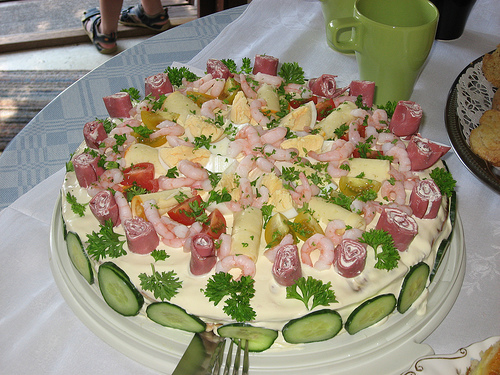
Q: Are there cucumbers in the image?
A: Yes, there is a cucumber.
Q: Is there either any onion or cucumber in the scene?
A: Yes, there is a cucumber.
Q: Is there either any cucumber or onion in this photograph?
A: Yes, there is a cucumber.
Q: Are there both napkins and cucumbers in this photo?
A: No, there is a cucumber but no napkins.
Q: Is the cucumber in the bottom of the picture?
A: Yes, the cucumber is in the bottom of the image.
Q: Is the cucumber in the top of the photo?
A: No, the cucumber is in the bottom of the image.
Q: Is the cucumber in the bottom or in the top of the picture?
A: The cucumber is in the bottom of the image.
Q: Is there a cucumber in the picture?
A: Yes, there is a cucumber.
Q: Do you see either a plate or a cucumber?
A: Yes, there is a cucumber.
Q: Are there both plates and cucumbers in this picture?
A: Yes, there are both a cucumber and a plate.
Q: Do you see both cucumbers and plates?
A: Yes, there are both a cucumber and a plate.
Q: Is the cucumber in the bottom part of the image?
A: Yes, the cucumber is in the bottom of the image.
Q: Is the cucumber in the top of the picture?
A: No, the cucumber is in the bottom of the image.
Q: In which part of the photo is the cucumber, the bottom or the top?
A: The cucumber is in the bottom of the image.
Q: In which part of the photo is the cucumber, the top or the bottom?
A: The cucumber is in the bottom of the image.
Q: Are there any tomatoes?
A: Yes, there are tomatoes.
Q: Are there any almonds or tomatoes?
A: Yes, there are tomatoes.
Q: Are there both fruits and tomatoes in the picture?
A: No, there are tomatoes but no fruits.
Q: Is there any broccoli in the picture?
A: No, there is no broccoli.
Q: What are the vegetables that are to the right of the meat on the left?
A: The vegetables are tomatoes.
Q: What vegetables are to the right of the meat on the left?
A: The vegetables are tomatoes.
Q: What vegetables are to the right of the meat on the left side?
A: The vegetables are tomatoes.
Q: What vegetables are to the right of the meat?
A: The vegetables are tomatoes.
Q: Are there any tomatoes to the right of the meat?
A: Yes, there are tomatoes to the right of the meat.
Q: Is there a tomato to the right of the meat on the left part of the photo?
A: Yes, there are tomatoes to the right of the meat.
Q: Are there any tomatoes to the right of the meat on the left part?
A: Yes, there are tomatoes to the right of the meat.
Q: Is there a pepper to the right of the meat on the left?
A: No, there are tomatoes to the right of the meat.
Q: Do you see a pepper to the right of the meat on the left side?
A: No, there are tomatoes to the right of the meat.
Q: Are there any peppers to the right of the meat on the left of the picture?
A: No, there are tomatoes to the right of the meat.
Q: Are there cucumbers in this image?
A: Yes, there is a cucumber.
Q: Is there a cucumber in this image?
A: Yes, there is a cucumber.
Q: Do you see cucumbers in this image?
A: Yes, there is a cucumber.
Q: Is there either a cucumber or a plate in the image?
A: Yes, there is a cucumber.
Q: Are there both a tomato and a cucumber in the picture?
A: Yes, there are both a cucumber and a tomato.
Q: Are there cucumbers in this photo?
A: Yes, there is a cucumber.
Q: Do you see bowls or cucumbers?
A: Yes, there is a cucumber.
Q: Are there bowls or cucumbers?
A: Yes, there is a cucumber.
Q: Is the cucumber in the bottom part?
A: Yes, the cucumber is in the bottom of the image.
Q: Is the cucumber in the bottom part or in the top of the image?
A: The cucumber is in the bottom of the image.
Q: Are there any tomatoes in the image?
A: Yes, there are tomatoes.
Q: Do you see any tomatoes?
A: Yes, there are tomatoes.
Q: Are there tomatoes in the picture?
A: Yes, there are tomatoes.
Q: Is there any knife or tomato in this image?
A: Yes, there are tomatoes.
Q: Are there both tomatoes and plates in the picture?
A: Yes, there are both tomatoes and a plate.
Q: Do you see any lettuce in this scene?
A: No, there is no lettuce.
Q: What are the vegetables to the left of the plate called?
A: The vegetables are tomatoes.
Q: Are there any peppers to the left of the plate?
A: No, there are tomatoes to the left of the plate.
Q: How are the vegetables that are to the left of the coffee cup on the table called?
A: The vegetables are tomatoes.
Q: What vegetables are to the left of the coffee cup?
A: The vegetables are tomatoes.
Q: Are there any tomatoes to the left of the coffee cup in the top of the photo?
A: Yes, there are tomatoes to the left of the coffee cup.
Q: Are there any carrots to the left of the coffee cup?
A: No, there are tomatoes to the left of the coffee cup.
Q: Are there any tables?
A: Yes, there is a table.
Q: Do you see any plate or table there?
A: Yes, there is a table.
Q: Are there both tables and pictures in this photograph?
A: No, there is a table but no pictures.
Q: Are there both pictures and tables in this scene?
A: No, there is a table but no pictures.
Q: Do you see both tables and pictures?
A: No, there is a table but no pictures.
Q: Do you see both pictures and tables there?
A: No, there is a table but no pictures.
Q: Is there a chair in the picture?
A: No, there are no chairs.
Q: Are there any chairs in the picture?
A: No, there are no chairs.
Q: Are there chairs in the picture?
A: No, there are no chairs.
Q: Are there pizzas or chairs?
A: No, there are no chairs or pizzas.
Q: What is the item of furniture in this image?
A: The piece of furniture is a table.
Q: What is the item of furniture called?
A: The piece of furniture is a table.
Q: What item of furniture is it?
A: The piece of furniture is a table.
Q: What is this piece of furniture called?
A: This is a table.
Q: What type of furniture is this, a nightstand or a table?
A: This is a table.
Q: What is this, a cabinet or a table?
A: This is a table.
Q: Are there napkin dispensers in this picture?
A: No, there are no napkin dispensers.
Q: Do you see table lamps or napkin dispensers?
A: No, there are no napkin dispensers or table lamps.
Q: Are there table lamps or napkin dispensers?
A: No, there are no napkin dispensers or table lamps.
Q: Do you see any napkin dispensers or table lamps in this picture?
A: No, there are no napkin dispensers or table lamps.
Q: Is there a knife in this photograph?
A: Yes, there is a knife.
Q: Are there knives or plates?
A: Yes, there is a knife.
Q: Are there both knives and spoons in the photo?
A: No, there is a knife but no spoons.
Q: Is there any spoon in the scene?
A: No, there are no spoons.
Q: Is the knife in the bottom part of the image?
A: Yes, the knife is in the bottom of the image.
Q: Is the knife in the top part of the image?
A: No, the knife is in the bottom of the image.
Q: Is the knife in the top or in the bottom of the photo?
A: The knife is in the bottom of the image.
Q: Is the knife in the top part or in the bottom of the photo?
A: The knife is in the bottom of the image.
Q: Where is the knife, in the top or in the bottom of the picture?
A: The knife is in the bottom of the image.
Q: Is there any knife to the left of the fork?
A: Yes, there is a knife to the left of the fork.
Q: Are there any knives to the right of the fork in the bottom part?
A: No, the knife is to the left of the fork.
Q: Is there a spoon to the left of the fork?
A: No, there is a knife to the left of the fork.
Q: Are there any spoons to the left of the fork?
A: No, there is a knife to the left of the fork.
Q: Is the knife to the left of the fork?
A: Yes, the knife is to the left of the fork.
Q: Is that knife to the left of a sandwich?
A: No, the knife is to the left of the fork.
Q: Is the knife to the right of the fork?
A: No, the knife is to the left of the fork.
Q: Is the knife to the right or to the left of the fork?
A: The knife is to the left of the fork.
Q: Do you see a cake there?
A: Yes, there is a cake.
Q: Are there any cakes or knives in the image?
A: Yes, there is a cake.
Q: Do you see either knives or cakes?
A: Yes, there is a cake.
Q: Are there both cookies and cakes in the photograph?
A: Yes, there are both a cake and a cookie.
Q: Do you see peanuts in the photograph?
A: No, there are no peanuts.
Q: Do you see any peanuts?
A: No, there are no peanuts.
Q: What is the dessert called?
A: The dessert is a cake.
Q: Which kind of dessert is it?
A: The dessert is a cake.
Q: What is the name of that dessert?
A: This is a cake.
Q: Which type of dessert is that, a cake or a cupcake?
A: This is a cake.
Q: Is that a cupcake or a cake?
A: That is a cake.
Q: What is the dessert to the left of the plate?
A: The dessert is a cake.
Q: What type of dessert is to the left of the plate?
A: The dessert is a cake.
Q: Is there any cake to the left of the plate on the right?
A: Yes, there is a cake to the left of the plate.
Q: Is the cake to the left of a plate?
A: Yes, the cake is to the left of a plate.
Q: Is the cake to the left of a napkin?
A: No, the cake is to the left of a plate.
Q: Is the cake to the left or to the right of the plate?
A: The cake is to the left of the plate.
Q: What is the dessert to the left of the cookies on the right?
A: The dessert is a cake.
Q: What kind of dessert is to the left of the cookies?
A: The dessert is a cake.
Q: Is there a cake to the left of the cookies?
A: Yes, there is a cake to the left of the cookies.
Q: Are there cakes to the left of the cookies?
A: Yes, there is a cake to the left of the cookies.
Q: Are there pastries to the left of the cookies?
A: No, there is a cake to the left of the cookies.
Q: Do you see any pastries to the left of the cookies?
A: No, there is a cake to the left of the cookies.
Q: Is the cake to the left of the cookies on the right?
A: Yes, the cake is to the left of the cookies.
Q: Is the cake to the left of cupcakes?
A: No, the cake is to the left of the cookies.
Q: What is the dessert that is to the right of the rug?
A: The dessert is a cake.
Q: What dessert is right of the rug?
A: The dessert is a cake.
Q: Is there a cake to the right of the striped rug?
A: Yes, there is a cake to the right of the rug.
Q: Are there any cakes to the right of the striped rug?
A: Yes, there is a cake to the right of the rug.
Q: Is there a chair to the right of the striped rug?
A: No, there is a cake to the right of the rug.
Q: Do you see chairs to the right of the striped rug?
A: No, there is a cake to the right of the rug.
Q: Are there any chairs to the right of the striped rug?
A: No, there is a cake to the right of the rug.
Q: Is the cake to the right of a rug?
A: Yes, the cake is to the right of a rug.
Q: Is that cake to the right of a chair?
A: No, the cake is to the right of a rug.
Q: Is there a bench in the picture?
A: No, there are no benches.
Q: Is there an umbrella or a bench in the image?
A: No, there are no benches or umbrellas.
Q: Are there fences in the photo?
A: No, there are no fences.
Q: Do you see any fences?
A: No, there are no fences.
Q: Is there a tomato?
A: Yes, there is a tomato.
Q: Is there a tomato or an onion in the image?
A: Yes, there is a tomato.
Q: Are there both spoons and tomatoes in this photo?
A: No, there is a tomato but no spoons.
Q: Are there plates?
A: Yes, there is a plate.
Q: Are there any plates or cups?
A: Yes, there is a plate.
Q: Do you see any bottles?
A: No, there are no bottles.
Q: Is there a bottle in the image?
A: No, there are no bottles.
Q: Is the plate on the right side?
A: Yes, the plate is on the right of the image.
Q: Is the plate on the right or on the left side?
A: The plate is on the right of the image.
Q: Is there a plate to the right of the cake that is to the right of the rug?
A: Yes, there is a plate to the right of the cake.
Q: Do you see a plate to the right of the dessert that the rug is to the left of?
A: Yes, there is a plate to the right of the cake.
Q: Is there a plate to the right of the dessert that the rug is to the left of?
A: Yes, there is a plate to the right of the cake.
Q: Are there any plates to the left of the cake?
A: No, the plate is to the right of the cake.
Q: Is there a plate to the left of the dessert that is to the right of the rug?
A: No, the plate is to the right of the cake.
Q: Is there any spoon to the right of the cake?
A: No, there is a plate to the right of the cake.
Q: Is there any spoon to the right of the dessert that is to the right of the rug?
A: No, there is a plate to the right of the cake.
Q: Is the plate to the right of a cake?
A: Yes, the plate is to the right of a cake.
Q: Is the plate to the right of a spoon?
A: No, the plate is to the right of a cake.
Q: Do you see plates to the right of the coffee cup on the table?
A: Yes, there is a plate to the right of the coffee cup.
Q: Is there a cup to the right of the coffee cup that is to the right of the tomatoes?
A: No, there is a plate to the right of the coffee cup.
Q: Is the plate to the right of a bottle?
A: No, the plate is to the right of the coffee cup.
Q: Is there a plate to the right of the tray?
A: Yes, there is a plate to the right of the tray.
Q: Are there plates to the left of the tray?
A: No, the plate is to the right of the tray.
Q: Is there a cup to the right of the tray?
A: No, there is a plate to the right of the tray.